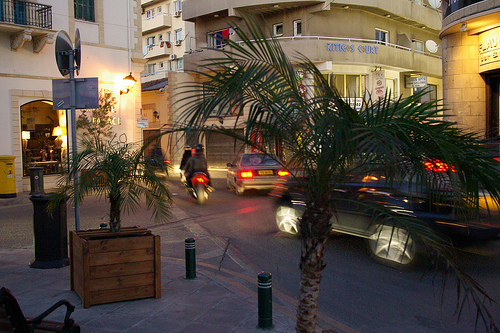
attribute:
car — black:
[270, 160, 499, 265]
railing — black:
[2, 0, 52, 29]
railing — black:
[193, 33, 440, 40]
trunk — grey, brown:
[238, 160, 323, 225]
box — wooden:
[65, 226, 162, 306]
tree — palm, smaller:
[175, 14, 495, 304]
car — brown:
[214, 139, 324, 200]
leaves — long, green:
[112, 10, 499, 327]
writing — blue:
[327, 42, 380, 57]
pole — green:
[255, 269, 275, 328]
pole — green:
[183, 235, 196, 277]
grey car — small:
[230, 160, 295, 195]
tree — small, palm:
[137, 12, 499, 332]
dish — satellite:
[425, 39, 437, 54]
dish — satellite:
[427, 0, 439, 8]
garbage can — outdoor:
[16, 182, 75, 290]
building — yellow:
[137, 0, 197, 173]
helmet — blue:
[192, 140, 207, 151]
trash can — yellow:
[0, 152, 17, 199]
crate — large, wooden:
[68, 226, 158, 306]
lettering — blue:
[315, 40, 385, 55]